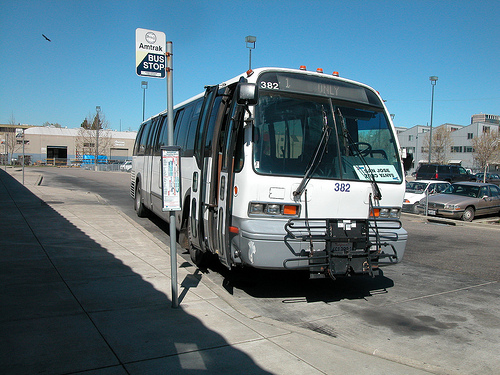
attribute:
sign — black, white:
[124, 18, 174, 81]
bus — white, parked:
[128, 68, 416, 285]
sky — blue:
[60, 4, 478, 28]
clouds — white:
[406, 110, 424, 119]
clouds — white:
[113, 116, 129, 126]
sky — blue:
[324, 12, 437, 44]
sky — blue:
[287, 13, 460, 55]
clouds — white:
[458, 93, 471, 107]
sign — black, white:
[130, 20, 177, 90]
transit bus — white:
[119, 48, 429, 342]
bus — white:
[118, 55, 408, 309]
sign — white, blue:
[127, 19, 181, 89]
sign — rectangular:
[128, 26, 166, 78]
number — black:
[330, 179, 346, 202]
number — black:
[339, 180, 355, 196]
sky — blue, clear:
[101, 8, 379, 95]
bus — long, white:
[116, 60, 432, 325]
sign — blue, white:
[128, 17, 166, 80]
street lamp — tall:
[418, 66, 450, 187]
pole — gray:
[150, 42, 190, 307]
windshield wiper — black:
[276, 124, 345, 218]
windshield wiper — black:
[332, 119, 388, 193]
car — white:
[388, 175, 449, 218]